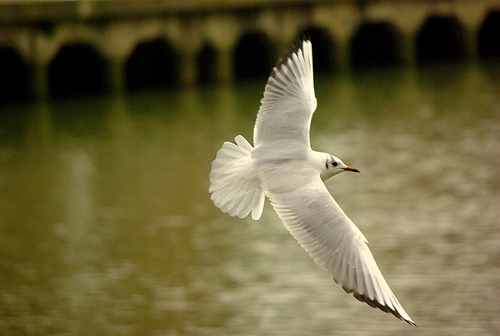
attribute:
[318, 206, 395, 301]
feathers — white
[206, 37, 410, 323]
bird — white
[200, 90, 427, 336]
bird — white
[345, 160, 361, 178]
beak — tip, black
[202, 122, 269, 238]
tail — white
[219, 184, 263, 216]
feathers — white